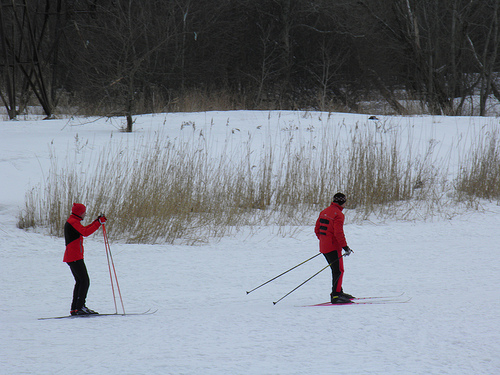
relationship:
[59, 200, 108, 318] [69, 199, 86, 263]
person wear red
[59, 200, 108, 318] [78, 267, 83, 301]
person wear black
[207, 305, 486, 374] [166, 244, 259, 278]
snow on ground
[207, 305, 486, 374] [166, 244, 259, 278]
snow covered ground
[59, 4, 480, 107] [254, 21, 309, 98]
trees without leaves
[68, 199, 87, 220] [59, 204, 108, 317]
hat on person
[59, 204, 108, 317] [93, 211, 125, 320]
skier with poles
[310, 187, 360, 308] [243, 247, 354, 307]
people with poles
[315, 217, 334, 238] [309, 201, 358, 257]
stripes on jacket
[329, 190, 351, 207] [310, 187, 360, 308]
hat on people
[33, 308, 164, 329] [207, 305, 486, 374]
skis on snow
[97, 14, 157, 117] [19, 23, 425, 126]
tree in distance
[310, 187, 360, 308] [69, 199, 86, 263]
people in red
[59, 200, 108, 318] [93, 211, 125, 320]
person have poles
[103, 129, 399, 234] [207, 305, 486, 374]
grass in snow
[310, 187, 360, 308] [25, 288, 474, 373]
people has sport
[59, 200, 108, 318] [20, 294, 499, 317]
person on trail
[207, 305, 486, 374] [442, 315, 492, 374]
snow not fresh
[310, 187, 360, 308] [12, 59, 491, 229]
people in wilderness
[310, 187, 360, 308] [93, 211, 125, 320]
people has poles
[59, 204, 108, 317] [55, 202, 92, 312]
person wearing suit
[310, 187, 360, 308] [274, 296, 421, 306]
people on skiis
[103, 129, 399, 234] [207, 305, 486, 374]
grass covers snow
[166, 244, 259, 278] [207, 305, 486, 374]
ground has snow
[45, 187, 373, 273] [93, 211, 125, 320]
people have poles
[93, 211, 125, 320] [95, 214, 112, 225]
poles in hands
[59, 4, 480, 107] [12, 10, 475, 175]
trees in background